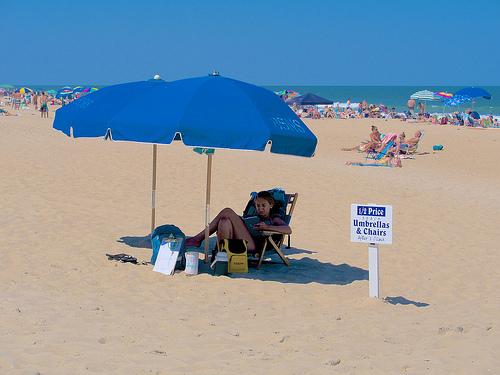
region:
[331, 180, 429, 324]
a sign on the beach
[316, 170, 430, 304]
a blue and white sign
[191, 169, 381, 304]
a woman sitting on a beach chair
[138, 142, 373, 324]
a woman sitting at the beach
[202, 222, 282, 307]
a yellow and black bag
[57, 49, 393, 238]
a blue umbrella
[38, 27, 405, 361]
a blue umbrella on the beach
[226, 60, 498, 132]
the ocean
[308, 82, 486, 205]
people on the beach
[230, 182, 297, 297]
a beach chair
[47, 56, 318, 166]
two blue beach umbrellas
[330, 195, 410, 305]
a white wooden sign stuck in the sand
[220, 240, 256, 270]
a yellow and black bag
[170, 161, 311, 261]
woman sitting in a beach chair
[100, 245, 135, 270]
black sandals on the sand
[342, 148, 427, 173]
woman laying down on a blue beach towel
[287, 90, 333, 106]
a blue canopy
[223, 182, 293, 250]
woman reading a book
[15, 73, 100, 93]
a row of colorful beach umbrellas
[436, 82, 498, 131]
people sitting under a blue umbrella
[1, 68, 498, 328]
family beach, w/ families on it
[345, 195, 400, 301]
'one half price umbrellas & chairs' w/ a whole mess of blurry writing between+beneath it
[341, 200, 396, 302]
'one half price' sign written in blue on white, when it's not in white in a blue box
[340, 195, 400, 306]
'one half price' sign on white wooden stick implanted - rather: stuck - in beach sand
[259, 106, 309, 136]
the '85ns' that is the number of a 'one half price' umbrella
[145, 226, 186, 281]
sign up sheet for 'one half price' umbrellas, maybe chairs even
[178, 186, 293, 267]
woman reading book, waiting on customers appearing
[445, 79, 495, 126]
a probable 'one half price' umbrella in the middle distance, close to the sea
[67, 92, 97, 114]
the blurry number printed, also in white, on the second 'one half price' umbrella over 'one half price' chaired reader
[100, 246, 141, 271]
two sandals, black, carelessly thrown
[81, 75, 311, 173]
The umbrella is blue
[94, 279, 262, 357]
The sand is brown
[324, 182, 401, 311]
The sign is in the sand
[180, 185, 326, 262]
The woman is reading a book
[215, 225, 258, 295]
The item is yellow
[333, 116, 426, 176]
People are in the back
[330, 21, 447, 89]
The sky is clear and blue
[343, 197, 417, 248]
The sign is white and blue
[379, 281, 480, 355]
The sand has a shadow on it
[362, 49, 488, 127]
The people are using umbrellas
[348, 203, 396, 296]
blue and white sign in the sand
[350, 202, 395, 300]
blue and white umbrella and chair sign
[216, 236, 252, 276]
black and yellow bag on the sand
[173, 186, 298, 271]
young woman sitting under an umbrella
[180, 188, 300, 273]
young woman sitting in a chair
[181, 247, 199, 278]
white and blue container on the sand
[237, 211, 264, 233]
book in the young woman's hands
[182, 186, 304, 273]
young woman sitting down on a chair and reading a book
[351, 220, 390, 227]
blue text on a sign reading umbrellas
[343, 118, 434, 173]
a group of people relaxing at the beach